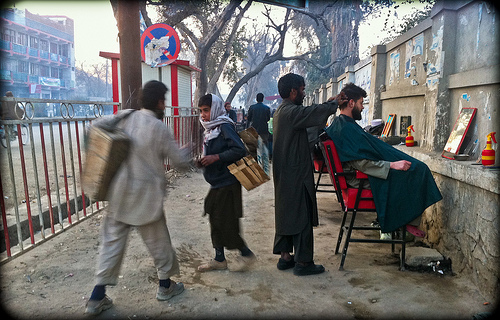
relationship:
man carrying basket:
[79, 78, 198, 317] [80, 123, 130, 202]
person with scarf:
[196, 93, 271, 272] [193, 93, 233, 137]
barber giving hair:
[272, 72, 348, 276] [339, 82, 368, 111]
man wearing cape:
[323, 82, 442, 233] [324, 112, 443, 234]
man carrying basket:
[79, 78, 198, 317] [76, 118, 126, 205]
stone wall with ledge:
[441, 17, 497, 101] [391, 141, 498, 193]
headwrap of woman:
[199, 93, 235, 141] [189, 85, 262, 273]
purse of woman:
[224, 151, 271, 191] [192, 90, 257, 275]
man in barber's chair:
[323, 82, 442, 233] [315, 139, 408, 271]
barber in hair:
[262, 67, 353, 278] [343, 86, 357, 95]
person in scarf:
[196, 93, 271, 272] [196, 89, 243, 136]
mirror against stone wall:
[445, 109, 475, 151] [447, 17, 497, 107]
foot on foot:
[84, 294, 114, 315] [82, 272, 116, 317]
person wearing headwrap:
[184, 91, 234, 141] [196, 90, 234, 138]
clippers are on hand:
[331, 93, 351, 110] [329, 91, 351, 111]